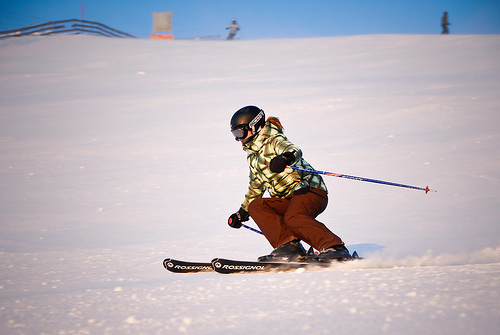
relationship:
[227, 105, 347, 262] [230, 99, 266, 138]
man wearing helmet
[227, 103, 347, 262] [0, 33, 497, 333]
man skiing down slope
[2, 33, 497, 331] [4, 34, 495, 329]
mountain covered with snow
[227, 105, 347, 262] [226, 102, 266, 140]
man wearing helmet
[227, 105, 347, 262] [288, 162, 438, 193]
man holding ski pole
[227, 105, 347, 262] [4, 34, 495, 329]
man skiing in snow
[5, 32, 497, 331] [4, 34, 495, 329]
ground covered in snow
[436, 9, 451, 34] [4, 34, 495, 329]
person walking in snow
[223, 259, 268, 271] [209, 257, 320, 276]
letters on ski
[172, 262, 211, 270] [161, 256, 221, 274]
letters on ski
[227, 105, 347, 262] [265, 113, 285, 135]
man has hair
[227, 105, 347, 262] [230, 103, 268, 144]
man wearing helmet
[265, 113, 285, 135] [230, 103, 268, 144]
hair hanging out of helmet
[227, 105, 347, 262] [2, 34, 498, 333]
man skiing down hill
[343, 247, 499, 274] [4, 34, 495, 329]
tracks in snow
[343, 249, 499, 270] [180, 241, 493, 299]
tracks of snow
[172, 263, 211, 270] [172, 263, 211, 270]
letters spelling letters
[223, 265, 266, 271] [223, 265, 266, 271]
letters spelling letters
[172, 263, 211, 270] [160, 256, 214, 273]
letters printed on ski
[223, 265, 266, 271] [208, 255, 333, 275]
letters printed on ski